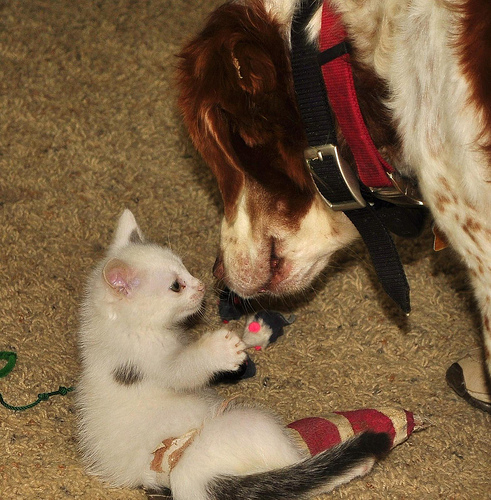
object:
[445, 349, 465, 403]
tip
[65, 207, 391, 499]
kitten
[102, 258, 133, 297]
inside ear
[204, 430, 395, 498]
tail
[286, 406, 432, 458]
toy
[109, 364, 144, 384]
spot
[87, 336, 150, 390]
shoulder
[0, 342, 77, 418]
string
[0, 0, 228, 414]
ground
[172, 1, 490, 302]
dog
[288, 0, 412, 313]
collar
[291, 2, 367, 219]
collar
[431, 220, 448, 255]
tags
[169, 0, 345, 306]
face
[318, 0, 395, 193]
collar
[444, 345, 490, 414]
tennis shoe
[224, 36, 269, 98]
something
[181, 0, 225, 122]
hair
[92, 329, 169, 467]
fur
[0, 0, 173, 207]
carpet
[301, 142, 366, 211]
buckle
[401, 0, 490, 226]
fur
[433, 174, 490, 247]
spots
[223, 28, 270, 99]
ear